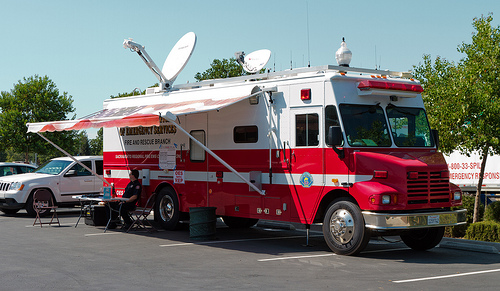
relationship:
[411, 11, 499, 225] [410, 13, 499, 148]
tree has leaves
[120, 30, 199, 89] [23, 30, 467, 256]
dish are on truck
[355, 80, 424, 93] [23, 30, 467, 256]
lights are on truck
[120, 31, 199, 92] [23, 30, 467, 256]
dish on ambulance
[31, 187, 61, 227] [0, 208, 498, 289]
chair in parking lot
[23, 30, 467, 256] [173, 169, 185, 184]
ambulance has sign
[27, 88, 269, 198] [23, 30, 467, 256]
awning on side of ambulance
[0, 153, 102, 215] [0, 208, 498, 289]
car in lot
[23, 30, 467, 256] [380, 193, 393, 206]
truck has headlight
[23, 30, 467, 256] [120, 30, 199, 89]
truck has dish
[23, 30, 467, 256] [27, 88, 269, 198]
truck has awning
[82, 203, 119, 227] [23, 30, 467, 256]
container next to truck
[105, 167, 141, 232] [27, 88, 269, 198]
man sitting under awning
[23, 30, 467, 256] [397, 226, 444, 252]
truck has wheel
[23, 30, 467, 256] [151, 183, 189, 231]
truck has wheel